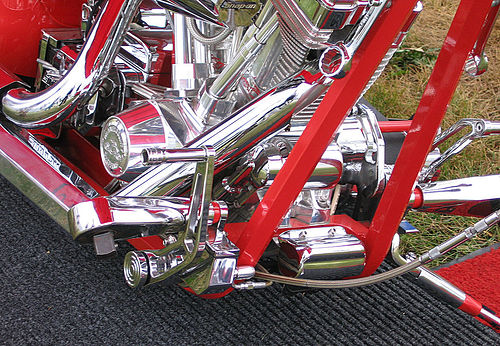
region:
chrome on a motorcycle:
[85, 10, 372, 264]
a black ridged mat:
[234, 300, 439, 342]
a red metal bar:
[321, 86, 342, 128]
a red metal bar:
[416, 82, 440, 159]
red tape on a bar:
[463, 291, 484, 317]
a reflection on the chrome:
[56, 63, 101, 99]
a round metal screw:
[123, 247, 145, 289]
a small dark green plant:
[393, 47, 421, 76]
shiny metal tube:
[191, 21, 224, 47]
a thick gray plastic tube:
[280, 261, 422, 293]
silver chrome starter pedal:
[115, 140, 219, 292]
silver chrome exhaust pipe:
[2, 0, 149, 136]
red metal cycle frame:
[237, 0, 498, 298]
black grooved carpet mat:
[2, 160, 498, 344]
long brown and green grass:
[340, 3, 499, 258]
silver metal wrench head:
[316, 40, 352, 83]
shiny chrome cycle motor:
[31, 0, 443, 307]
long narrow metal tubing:
[253, 207, 498, 295]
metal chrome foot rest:
[66, 193, 231, 263]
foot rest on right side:
[406, 167, 498, 232]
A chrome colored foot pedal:
[121, 141, 214, 291]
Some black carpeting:
[0, 175, 499, 344]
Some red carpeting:
[429, 248, 499, 330]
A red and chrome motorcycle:
[2, 1, 498, 295]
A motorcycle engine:
[93, 4, 423, 196]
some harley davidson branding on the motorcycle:
[103, 133, 123, 165]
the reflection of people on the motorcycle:
[21, 79, 85, 121]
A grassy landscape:
[361, 3, 498, 271]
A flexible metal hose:
[252, 253, 432, 288]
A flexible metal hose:
[181, 16, 233, 49]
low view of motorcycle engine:
[30, 20, 487, 320]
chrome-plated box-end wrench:
[282, 0, 403, 90]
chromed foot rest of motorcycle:
[90, 123, 225, 299]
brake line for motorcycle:
[212, 198, 486, 304]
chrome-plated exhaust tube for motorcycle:
[29, 2, 165, 141]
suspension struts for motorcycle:
[215, 7, 477, 297]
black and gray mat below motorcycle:
[0, 205, 471, 341]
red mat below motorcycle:
[407, 225, 492, 340]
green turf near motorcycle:
[260, 0, 490, 270]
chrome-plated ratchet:
[49, 174, 236, 276]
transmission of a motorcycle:
[102, 47, 407, 302]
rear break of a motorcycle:
[125, 132, 224, 282]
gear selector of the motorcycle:
[418, 95, 498, 192]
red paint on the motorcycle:
[14, 0, 72, 157]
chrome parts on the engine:
[108, 50, 262, 239]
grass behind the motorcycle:
[368, 38, 488, 193]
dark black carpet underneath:
[59, 293, 444, 345]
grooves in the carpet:
[27, 250, 142, 323]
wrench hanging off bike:
[299, 15, 392, 92]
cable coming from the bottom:
[248, 181, 498, 311]